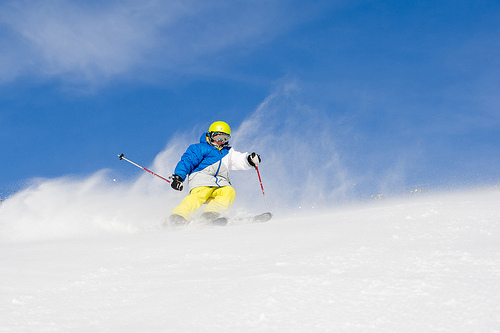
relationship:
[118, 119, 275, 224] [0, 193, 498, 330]
skier in snow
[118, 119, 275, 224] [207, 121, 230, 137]
skier has helmet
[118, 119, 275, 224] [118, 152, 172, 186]
skier has ski pole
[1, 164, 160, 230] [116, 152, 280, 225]
kicked up snow from skis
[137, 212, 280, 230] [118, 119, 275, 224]
snow skis from skier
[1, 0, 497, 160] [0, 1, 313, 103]
sky with light clouds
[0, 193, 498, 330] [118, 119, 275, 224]
snow with skier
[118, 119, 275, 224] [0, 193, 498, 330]
skier on snow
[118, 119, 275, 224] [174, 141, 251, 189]
skier with jacket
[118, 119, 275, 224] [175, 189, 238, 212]
skier has pants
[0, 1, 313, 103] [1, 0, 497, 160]
light clouds in sky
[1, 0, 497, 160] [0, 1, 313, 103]
sky has light clouds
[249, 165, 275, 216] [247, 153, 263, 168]
ski pole in hand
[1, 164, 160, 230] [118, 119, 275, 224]
kicked up snow frim skier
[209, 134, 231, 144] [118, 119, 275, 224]
goggles on skier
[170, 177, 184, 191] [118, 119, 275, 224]
glove on skier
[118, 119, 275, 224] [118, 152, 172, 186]
skier has pole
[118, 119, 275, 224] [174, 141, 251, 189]
skier has jacket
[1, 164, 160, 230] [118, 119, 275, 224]
kicked up snow from skier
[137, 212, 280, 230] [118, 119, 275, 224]
snow skis with skier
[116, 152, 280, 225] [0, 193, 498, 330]
skis in snow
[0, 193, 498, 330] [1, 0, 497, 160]
snow under sky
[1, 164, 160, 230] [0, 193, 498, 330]
kicked up snow above snow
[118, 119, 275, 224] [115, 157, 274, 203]
skier has ski poles